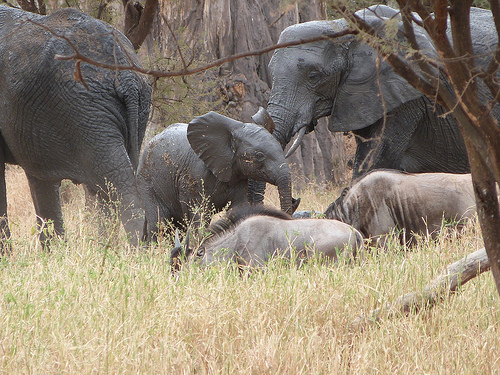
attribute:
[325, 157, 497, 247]
wild beast — grey 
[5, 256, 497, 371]
grass — brown 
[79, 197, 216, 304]
grass — long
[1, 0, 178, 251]
elephant — grey 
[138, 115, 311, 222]
elephant — smallest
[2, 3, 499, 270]
elephants — wild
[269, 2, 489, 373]
tree — bare , leafless 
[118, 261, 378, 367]
grass — green , tall 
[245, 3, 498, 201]
adult elephant — grey , large 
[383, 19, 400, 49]
leaves — green 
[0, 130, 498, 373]
grass — green 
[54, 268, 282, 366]
green grasses — tall , brown, green 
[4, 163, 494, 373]
grass — green , long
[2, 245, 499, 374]
grass — long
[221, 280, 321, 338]
grass — long